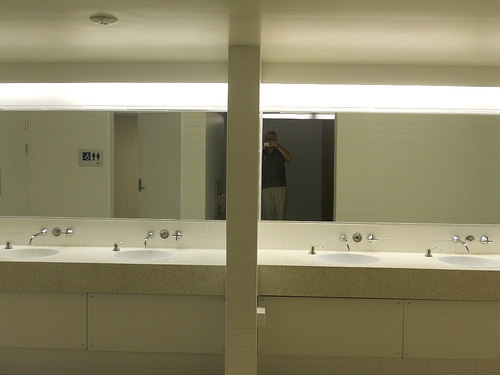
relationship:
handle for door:
[134, 176, 146, 195] [132, 111, 179, 217]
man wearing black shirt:
[261, 130, 292, 218] [261, 145, 286, 190]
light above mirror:
[0, 82, 500, 120] [262, 112, 497, 219]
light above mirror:
[0, 82, 500, 120] [3, 107, 221, 219]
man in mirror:
[261, 130, 292, 220] [0, 2, 497, 258]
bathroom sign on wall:
[79, 150, 103, 166] [10, 106, 119, 219]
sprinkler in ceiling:
[88, 12, 118, 26] [1, 0, 485, 89]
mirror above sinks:
[2, 108, 499, 225] [1, 243, 60, 260]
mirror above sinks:
[2, 108, 499, 225] [107, 246, 178, 261]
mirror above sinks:
[2, 108, 499, 225] [316, 249, 378, 267]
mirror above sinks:
[2, 108, 499, 225] [440, 247, 485, 271]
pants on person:
[263, 176, 290, 216] [257, 117, 297, 220]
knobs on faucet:
[48, 223, 67, 236] [25, 227, 49, 246]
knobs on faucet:
[52, 226, 62, 236] [141, 226, 157, 246]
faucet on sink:
[141, 226, 157, 246] [106, 245, 177, 265]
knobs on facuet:
[349, 230, 362, 245] [340, 230, 353, 250]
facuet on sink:
[340, 230, 353, 250] [319, 249, 381, 266]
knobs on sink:
[465, 232, 477, 244] [434, 250, 484, 267]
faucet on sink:
[449, 230, 473, 252] [434, 250, 484, 267]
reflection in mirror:
[262, 126, 292, 218] [262, 109, 338, 219]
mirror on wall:
[3, 107, 221, 219] [5, 65, 499, 240]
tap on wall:
[363, 229, 383, 244] [4, 217, 484, 255]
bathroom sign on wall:
[79, 150, 103, 166] [21, 109, 121, 220]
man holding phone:
[261, 130, 292, 220] [260, 138, 274, 149]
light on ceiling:
[0, 77, 499, 120] [2, 2, 498, 59]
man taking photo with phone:
[261, 130, 292, 220] [256, 135, 281, 150]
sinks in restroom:
[2, 229, 498, 269] [0, 1, 497, 365]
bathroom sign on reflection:
[79, 150, 103, 166] [30, 130, 157, 206]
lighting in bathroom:
[0, 81, 499, 112] [4, 3, 498, 372]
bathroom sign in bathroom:
[79, 150, 103, 166] [4, 3, 498, 372]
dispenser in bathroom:
[305, 242, 327, 261] [4, 3, 498, 372]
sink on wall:
[324, 232, 384, 269] [310, 220, 403, 258]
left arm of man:
[270, 142, 291, 161] [258, 131, 292, 215]